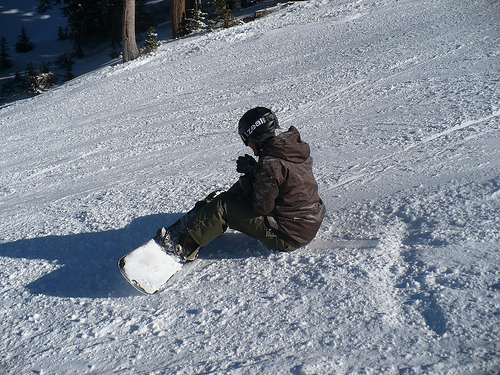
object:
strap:
[240, 112, 273, 142]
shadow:
[1, 211, 175, 299]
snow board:
[127, 183, 238, 290]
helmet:
[237, 105, 282, 147]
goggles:
[239, 136, 250, 147]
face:
[245, 132, 264, 156]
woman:
[153, 103, 326, 264]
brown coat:
[237, 125, 327, 247]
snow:
[0, 0, 497, 375]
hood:
[261, 126, 312, 162]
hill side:
[0, 0, 497, 374]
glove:
[234, 153, 260, 175]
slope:
[0, 1, 497, 371]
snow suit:
[173, 126, 331, 253]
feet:
[117, 220, 199, 296]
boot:
[156, 224, 198, 262]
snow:
[131, 238, 183, 285]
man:
[155, 105, 328, 263]